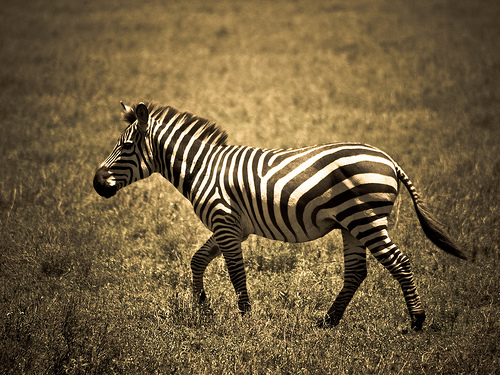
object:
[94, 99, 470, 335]
zebra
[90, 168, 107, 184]
nose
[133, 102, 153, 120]
ear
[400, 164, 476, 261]
tail